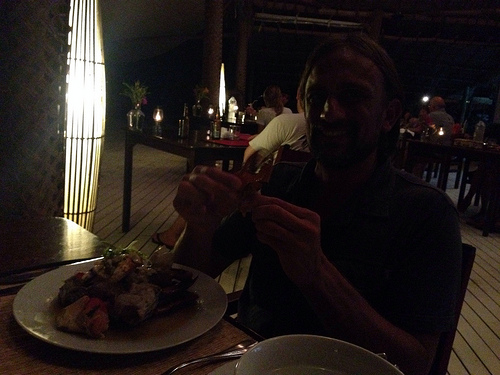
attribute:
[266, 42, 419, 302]
man — smiling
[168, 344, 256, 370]
utensils — piece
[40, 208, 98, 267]
table — wood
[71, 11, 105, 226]
light — white, bright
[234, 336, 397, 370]
bowl — large, empty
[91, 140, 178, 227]
floor — wood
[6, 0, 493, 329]
restaurant — dark, inside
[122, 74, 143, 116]
plant — green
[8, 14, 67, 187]
fence — white, wood,  lattice design 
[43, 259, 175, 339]
meats — different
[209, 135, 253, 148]
place — mat, red 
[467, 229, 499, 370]
floors — white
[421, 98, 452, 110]
bald — man